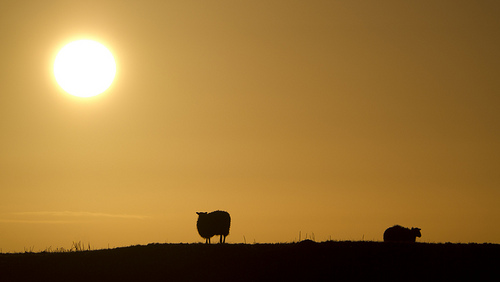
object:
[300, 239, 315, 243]
pile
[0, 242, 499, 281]
ground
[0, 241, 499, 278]
grass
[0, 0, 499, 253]
sky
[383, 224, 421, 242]
sheep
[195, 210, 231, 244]
sheep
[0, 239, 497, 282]
hill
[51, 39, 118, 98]
sun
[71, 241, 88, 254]
grass blades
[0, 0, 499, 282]
picture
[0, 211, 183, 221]
clouds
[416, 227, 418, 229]
ears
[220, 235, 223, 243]
legs